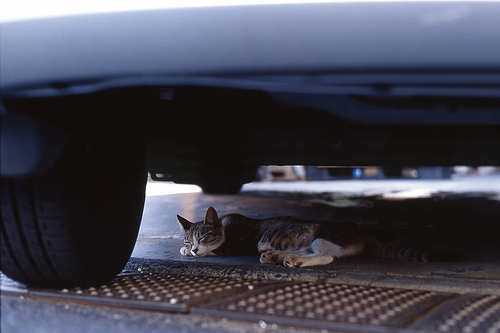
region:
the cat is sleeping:
[172, 204, 377, 296]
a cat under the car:
[49, 25, 353, 322]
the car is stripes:
[186, 208, 390, 305]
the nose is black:
[178, 237, 210, 256]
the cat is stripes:
[126, 194, 351, 293]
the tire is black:
[26, 158, 133, 312]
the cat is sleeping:
[165, 185, 467, 310]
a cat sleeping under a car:
[16, 70, 438, 324]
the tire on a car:
[0, 184, 186, 286]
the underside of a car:
[9, 53, 499, 300]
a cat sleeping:
[171, 201, 484, 291]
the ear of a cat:
[197, 205, 222, 227]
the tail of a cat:
[368, 233, 479, 273]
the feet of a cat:
[256, 243, 341, 273]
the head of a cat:
[168, 205, 223, 260]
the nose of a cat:
[188, 248, 202, 255]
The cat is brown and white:
[174, 211, 370, 267]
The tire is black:
[6, 185, 123, 280]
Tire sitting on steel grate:
[6, 233, 173, 299]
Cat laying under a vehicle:
[173, 205, 369, 272]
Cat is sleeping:
[171, 208, 370, 271]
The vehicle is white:
[9, 24, 492, 53]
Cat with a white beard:
[173, 207, 223, 262]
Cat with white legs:
[257, 235, 343, 270]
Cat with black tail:
[362, 236, 468, 266]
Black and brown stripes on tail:
[363, 238, 463, 264]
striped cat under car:
[166, 211, 343, 281]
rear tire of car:
[13, 182, 173, 309]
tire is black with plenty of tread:
[13, 204, 156, 260]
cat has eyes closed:
[175, 225, 215, 262]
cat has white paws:
[275, 246, 355, 262]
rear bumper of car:
[55, 22, 191, 74]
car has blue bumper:
[128, 38, 495, 85]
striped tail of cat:
[375, 235, 455, 276]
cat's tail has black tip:
[426, 243, 461, 269]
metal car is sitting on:
[136, 280, 224, 330]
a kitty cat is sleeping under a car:
[7, 33, 495, 329]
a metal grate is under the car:
[3, 258, 498, 332]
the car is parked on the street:
[6, 80, 496, 319]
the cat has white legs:
[257, 240, 338, 267]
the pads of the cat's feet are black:
[255, 245, 304, 273]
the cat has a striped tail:
[365, 237, 463, 270]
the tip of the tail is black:
[418, 243, 468, 268]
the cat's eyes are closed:
[171, 207, 226, 258]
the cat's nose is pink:
[190, 245, 199, 252]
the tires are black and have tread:
[1, 173, 123, 288]